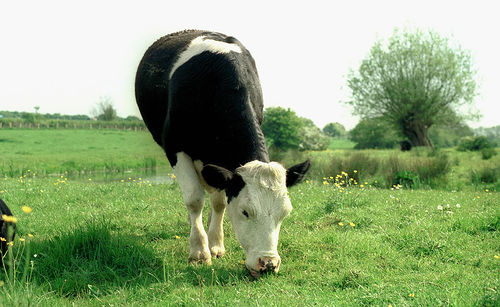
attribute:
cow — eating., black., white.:
[132, 29, 313, 279]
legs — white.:
[170, 152, 232, 270]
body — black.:
[134, 27, 274, 187]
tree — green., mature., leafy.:
[346, 29, 479, 149]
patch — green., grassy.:
[11, 218, 171, 298]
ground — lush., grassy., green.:
[4, 130, 493, 305]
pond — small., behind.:
[4, 154, 176, 190]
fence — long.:
[1, 115, 149, 138]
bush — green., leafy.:
[265, 106, 324, 158]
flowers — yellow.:
[0, 203, 40, 257]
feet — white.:
[184, 241, 229, 270]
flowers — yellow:
[316, 164, 366, 194]